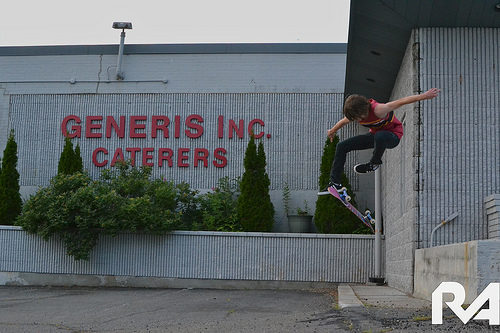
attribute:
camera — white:
[111, 21, 133, 36]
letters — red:
[63, 110, 266, 171]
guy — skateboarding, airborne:
[325, 91, 435, 181]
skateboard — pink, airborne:
[326, 187, 376, 229]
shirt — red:
[361, 103, 405, 138]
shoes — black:
[311, 161, 379, 198]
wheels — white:
[339, 188, 381, 221]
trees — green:
[5, 131, 357, 231]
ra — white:
[431, 282, 498, 325]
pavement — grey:
[5, 278, 355, 332]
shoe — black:
[354, 161, 379, 175]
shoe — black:
[316, 179, 347, 195]